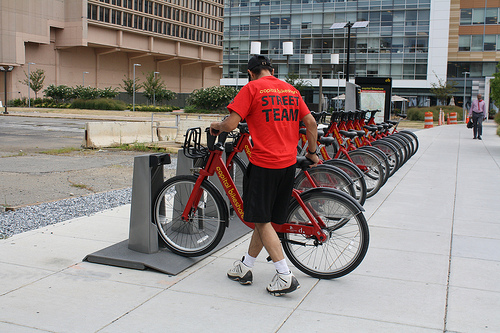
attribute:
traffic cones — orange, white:
[414, 98, 471, 128]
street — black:
[258, 96, 319, 128]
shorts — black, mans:
[233, 152, 294, 226]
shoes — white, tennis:
[272, 272, 297, 294]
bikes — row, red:
[127, 105, 427, 284]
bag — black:
[464, 119, 474, 134]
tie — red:
[475, 96, 485, 111]